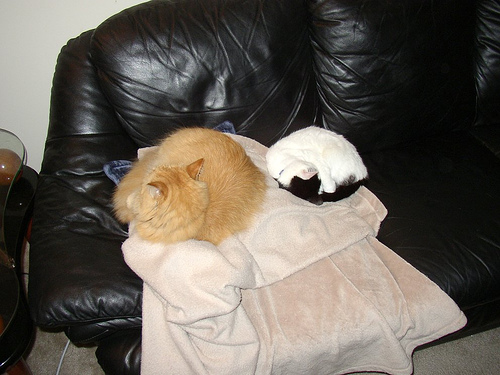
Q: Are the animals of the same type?
A: Yes, all the animals are cats.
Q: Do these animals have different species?
A: No, all the animals are cats.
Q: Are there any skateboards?
A: No, there are no skateboards.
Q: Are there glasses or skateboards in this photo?
A: No, there are no skateboards or glasses.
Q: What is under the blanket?
A: The jeans are under the blanket.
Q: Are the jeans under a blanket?
A: Yes, the jeans are under a blanket.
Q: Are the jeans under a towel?
A: No, the jeans are under a blanket.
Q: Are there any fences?
A: No, there are no fences.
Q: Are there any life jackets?
A: No, there are no life jackets.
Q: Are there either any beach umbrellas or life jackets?
A: No, there are no life jackets or beach umbrellas.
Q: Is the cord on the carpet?
A: Yes, the cord is on the carpet.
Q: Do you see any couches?
A: Yes, there is a couch.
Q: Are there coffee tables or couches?
A: Yes, there is a couch.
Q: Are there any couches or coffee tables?
A: Yes, there is a couch.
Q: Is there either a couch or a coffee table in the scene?
A: Yes, there is a couch.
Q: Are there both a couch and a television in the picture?
A: No, there is a couch but no televisions.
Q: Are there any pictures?
A: No, there are no pictures.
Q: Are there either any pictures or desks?
A: No, there are no pictures or desks.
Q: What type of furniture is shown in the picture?
A: The furniture is a couch.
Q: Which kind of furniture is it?
A: The piece of furniture is a couch.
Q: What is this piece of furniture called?
A: That is a couch.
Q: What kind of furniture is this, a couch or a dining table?
A: That is a couch.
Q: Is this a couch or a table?
A: This is a couch.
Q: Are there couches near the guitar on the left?
A: Yes, there is a couch near the guitar.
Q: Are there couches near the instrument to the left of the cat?
A: Yes, there is a couch near the guitar.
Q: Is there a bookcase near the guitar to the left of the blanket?
A: No, there is a couch near the guitar.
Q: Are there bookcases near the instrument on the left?
A: No, there is a couch near the guitar.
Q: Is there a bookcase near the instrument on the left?
A: No, there is a couch near the guitar.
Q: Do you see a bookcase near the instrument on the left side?
A: No, there is a couch near the guitar.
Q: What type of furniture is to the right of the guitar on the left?
A: The piece of furniture is a couch.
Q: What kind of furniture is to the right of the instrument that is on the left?
A: The piece of furniture is a couch.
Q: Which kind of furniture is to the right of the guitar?
A: The piece of furniture is a couch.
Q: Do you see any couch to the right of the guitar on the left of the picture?
A: Yes, there is a couch to the right of the guitar.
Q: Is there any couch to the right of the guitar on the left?
A: Yes, there is a couch to the right of the guitar.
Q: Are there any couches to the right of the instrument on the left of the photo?
A: Yes, there is a couch to the right of the guitar.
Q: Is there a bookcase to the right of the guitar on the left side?
A: No, there is a couch to the right of the guitar.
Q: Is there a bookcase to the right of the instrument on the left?
A: No, there is a couch to the right of the guitar.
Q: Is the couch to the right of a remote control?
A: No, the couch is to the right of a guitar.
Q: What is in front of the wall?
A: The couch is in front of the wall.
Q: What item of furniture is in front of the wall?
A: The piece of furniture is a couch.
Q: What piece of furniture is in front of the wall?
A: The piece of furniture is a couch.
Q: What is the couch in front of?
A: The couch is in front of the wall.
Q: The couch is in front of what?
A: The couch is in front of the wall.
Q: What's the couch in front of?
A: The couch is in front of the wall.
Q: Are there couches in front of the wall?
A: Yes, there is a couch in front of the wall.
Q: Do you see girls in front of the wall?
A: No, there is a couch in front of the wall.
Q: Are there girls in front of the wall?
A: No, there is a couch in front of the wall.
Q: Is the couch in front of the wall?
A: Yes, the couch is in front of the wall.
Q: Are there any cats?
A: Yes, there is a cat.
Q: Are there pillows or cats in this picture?
A: Yes, there is a cat.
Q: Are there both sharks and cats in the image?
A: No, there is a cat but no sharks.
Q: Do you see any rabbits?
A: No, there are no rabbits.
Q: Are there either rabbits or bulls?
A: No, there are no rabbits or bulls.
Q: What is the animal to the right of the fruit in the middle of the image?
A: The animal is a cat.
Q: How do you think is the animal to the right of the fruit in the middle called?
A: The animal is a cat.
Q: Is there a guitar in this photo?
A: Yes, there is a guitar.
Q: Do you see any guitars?
A: Yes, there is a guitar.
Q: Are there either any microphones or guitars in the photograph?
A: Yes, there is a guitar.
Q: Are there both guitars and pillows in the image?
A: Yes, there are both a guitar and a pillow.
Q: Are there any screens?
A: No, there are no screens.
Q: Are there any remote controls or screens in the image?
A: No, there are no screens or remote controls.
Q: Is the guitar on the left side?
A: Yes, the guitar is on the left of the image.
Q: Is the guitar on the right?
A: No, the guitar is on the left of the image.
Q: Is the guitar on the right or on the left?
A: The guitar is on the left of the image.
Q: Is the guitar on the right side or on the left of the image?
A: The guitar is on the left of the image.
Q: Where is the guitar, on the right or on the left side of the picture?
A: The guitar is on the left of the image.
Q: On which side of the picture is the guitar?
A: The guitar is on the left of the image.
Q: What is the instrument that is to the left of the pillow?
A: The instrument is a guitar.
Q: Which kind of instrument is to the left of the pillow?
A: The instrument is a guitar.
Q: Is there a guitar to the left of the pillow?
A: Yes, there is a guitar to the left of the pillow.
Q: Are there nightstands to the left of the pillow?
A: No, there is a guitar to the left of the pillow.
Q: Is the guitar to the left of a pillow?
A: Yes, the guitar is to the left of a pillow.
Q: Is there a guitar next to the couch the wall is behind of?
A: Yes, there is a guitar next to the couch.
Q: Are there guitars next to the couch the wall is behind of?
A: Yes, there is a guitar next to the couch.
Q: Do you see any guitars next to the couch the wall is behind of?
A: Yes, there is a guitar next to the couch.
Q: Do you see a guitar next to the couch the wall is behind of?
A: Yes, there is a guitar next to the couch.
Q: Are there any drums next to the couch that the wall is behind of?
A: No, there is a guitar next to the couch.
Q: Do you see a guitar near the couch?
A: Yes, there is a guitar near the couch.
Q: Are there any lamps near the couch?
A: No, there is a guitar near the couch.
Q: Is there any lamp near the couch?
A: No, there is a guitar near the couch.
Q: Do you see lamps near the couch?
A: No, there is a guitar near the couch.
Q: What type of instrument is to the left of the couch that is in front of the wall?
A: The instrument is a guitar.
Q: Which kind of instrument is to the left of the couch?
A: The instrument is a guitar.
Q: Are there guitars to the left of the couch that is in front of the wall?
A: Yes, there is a guitar to the left of the couch.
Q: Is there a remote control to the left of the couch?
A: No, there is a guitar to the left of the couch.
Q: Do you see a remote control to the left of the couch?
A: No, there is a guitar to the left of the couch.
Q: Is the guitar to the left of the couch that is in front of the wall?
A: Yes, the guitar is to the left of the couch.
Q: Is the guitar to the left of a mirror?
A: No, the guitar is to the left of the couch.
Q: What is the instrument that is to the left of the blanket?
A: The instrument is a guitar.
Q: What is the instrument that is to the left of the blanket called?
A: The instrument is a guitar.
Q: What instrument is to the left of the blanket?
A: The instrument is a guitar.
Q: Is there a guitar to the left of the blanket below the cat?
A: Yes, there is a guitar to the left of the blanket.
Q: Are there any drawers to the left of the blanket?
A: No, there is a guitar to the left of the blanket.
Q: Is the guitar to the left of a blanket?
A: Yes, the guitar is to the left of a blanket.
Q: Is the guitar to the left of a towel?
A: No, the guitar is to the left of a blanket.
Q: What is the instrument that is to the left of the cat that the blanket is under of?
A: The instrument is a guitar.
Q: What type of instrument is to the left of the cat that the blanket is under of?
A: The instrument is a guitar.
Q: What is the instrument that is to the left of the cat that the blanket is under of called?
A: The instrument is a guitar.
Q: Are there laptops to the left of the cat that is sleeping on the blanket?
A: No, there is a guitar to the left of the cat.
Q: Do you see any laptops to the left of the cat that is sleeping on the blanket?
A: No, there is a guitar to the left of the cat.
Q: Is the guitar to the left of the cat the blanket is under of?
A: Yes, the guitar is to the left of the cat.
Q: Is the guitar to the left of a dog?
A: No, the guitar is to the left of the cat.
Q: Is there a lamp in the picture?
A: No, there are no lamps.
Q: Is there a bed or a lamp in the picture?
A: No, there are no lamps or beds.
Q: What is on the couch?
A: The carpet is on the couch.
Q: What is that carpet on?
A: The carpet is on the couch.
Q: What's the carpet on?
A: The carpet is on the couch.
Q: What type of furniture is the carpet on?
A: The carpet is on the couch.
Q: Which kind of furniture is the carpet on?
A: The carpet is on the couch.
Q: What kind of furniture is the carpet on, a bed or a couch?
A: The carpet is on a couch.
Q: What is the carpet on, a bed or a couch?
A: The carpet is on a couch.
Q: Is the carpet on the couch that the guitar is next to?
A: Yes, the carpet is on the couch.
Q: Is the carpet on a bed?
A: No, the carpet is on the couch.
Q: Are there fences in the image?
A: No, there are no fences.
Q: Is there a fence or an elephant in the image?
A: No, there are no fences or elephants.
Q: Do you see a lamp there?
A: No, there are no lamps.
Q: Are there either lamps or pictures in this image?
A: No, there are no lamps or pictures.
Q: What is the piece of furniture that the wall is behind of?
A: The piece of furniture is a couch.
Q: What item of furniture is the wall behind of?
A: The wall is behind the couch.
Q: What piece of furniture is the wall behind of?
A: The wall is behind the couch.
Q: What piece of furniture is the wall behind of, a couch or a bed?
A: The wall is behind a couch.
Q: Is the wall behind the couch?
A: Yes, the wall is behind the couch.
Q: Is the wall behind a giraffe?
A: No, the wall is behind the couch.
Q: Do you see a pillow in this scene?
A: Yes, there is a pillow.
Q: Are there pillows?
A: Yes, there is a pillow.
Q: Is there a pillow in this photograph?
A: Yes, there is a pillow.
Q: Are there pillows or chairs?
A: Yes, there is a pillow.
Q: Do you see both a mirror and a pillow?
A: No, there is a pillow but no mirrors.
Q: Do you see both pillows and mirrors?
A: No, there is a pillow but no mirrors.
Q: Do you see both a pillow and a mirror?
A: No, there is a pillow but no mirrors.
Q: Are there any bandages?
A: No, there are no bandages.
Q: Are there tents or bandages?
A: No, there are no bandages or tents.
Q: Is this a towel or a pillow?
A: This is a pillow.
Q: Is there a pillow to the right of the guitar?
A: Yes, there is a pillow to the right of the guitar.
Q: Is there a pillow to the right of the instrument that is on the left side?
A: Yes, there is a pillow to the right of the guitar.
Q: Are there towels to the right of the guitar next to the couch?
A: No, there is a pillow to the right of the guitar.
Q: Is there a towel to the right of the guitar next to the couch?
A: No, there is a pillow to the right of the guitar.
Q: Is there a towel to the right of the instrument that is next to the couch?
A: No, there is a pillow to the right of the guitar.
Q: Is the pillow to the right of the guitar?
A: Yes, the pillow is to the right of the guitar.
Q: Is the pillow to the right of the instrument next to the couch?
A: Yes, the pillow is to the right of the guitar.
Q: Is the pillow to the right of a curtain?
A: No, the pillow is to the right of the guitar.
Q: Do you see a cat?
A: Yes, there is a cat.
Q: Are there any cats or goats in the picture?
A: Yes, there is a cat.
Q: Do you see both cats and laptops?
A: No, there is a cat but no laptops.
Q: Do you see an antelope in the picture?
A: No, there are no antelopes.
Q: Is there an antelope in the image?
A: No, there are no antelopes.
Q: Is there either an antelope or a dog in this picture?
A: No, there are no antelopes or dogs.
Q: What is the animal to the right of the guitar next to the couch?
A: The animal is a cat.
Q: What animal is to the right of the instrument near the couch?
A: The animal is a cat.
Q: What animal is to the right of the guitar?
A: The animal is a cat.